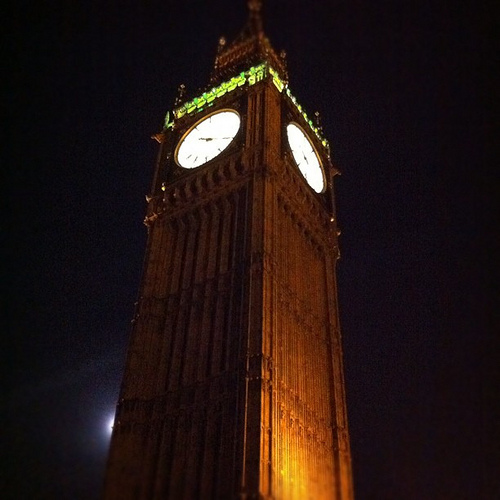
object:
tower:
[99, 0, 355, 499]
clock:
[172, 107, 242, 175]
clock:
[283, 121, 325, 197]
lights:
[173, 62, 266, 122]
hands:
[196, 133, 228, 143]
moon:
[104, 412, 116, 437]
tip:
[210, 0, 289, 88]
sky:
[2, 2, 497, 499]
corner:
[260, 57, 271, 81]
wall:
[100, 157, 262, 499]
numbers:
[176, 114, 238, 165]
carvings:
[156, 151, 255, 211]